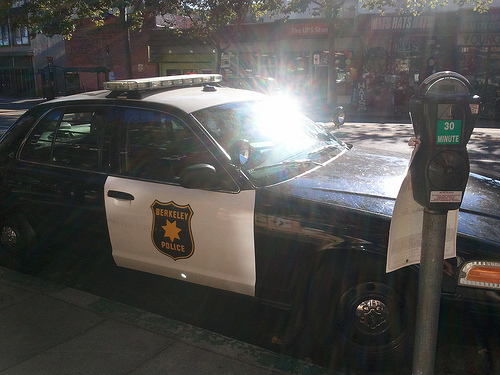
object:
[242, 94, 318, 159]
light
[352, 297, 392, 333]
hubcaps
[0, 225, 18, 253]
hubcaps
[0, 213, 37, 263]
rim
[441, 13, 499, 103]
storefront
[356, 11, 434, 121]
storefront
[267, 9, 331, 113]
storefront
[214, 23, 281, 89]
storefront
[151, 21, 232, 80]
storefront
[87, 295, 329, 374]
green paint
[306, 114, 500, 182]
ground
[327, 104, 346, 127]
car mirror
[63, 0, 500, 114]
buildings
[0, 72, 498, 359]
car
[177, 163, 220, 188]
mirror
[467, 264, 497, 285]
orange light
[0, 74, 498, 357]
vehicle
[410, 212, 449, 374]
pole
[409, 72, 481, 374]
meter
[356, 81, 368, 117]
sign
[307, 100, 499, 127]
sidewalk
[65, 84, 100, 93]
bench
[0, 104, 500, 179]
street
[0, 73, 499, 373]
police car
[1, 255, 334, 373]
sidewalk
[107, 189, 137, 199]
handle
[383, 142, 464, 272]
sign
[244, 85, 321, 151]
sunlight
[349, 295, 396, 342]
rim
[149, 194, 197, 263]
logo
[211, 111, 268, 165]
police officer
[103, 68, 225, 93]
lights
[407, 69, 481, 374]
parking meter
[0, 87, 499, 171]
road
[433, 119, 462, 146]
sign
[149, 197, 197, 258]
sticker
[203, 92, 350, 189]
windshield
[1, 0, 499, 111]
background